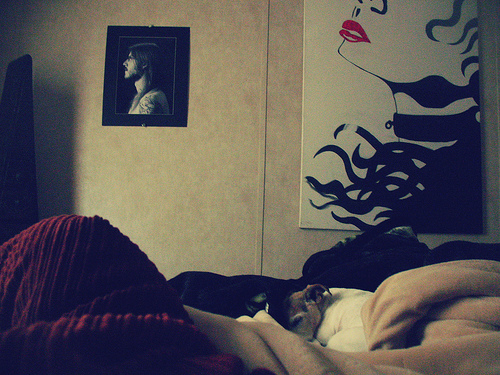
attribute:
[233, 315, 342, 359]
blanket — Tan 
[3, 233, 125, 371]
blanket — burgundy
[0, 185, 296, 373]
blanket — large , red 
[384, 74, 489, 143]
choker — black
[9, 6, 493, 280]
wall — beige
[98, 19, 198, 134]
picture — Large 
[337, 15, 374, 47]
lips — Red 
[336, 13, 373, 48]
lips — red 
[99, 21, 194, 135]
frame — black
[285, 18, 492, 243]
painting — black , white 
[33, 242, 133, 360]
blanket — red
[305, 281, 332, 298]
ear — brown 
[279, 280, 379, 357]
dog — sleeping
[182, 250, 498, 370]
blanket — beige